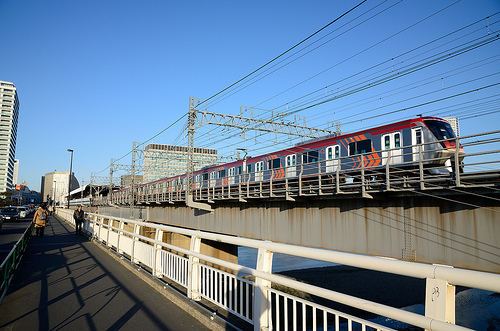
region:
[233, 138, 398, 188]
red and white train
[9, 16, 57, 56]
white clouds in blue sky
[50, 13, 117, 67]
white clouds in blue sky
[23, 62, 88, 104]
white clouds in blue sky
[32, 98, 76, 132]
white clouds in blue sky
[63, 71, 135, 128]
white clouds in blue sky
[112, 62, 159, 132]
white clouds in blue sky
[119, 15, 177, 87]
white clouds in blue sky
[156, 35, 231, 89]
white clouds in blue sky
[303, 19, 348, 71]
white clouds in blue sky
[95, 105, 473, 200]
red and grey train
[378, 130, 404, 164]
pair of white doors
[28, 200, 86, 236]
people walking on the sidewalk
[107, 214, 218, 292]
white guard rail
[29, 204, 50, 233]
person in a brown jacket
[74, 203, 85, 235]
person wearing black clothing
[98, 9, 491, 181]
numerous lines over the train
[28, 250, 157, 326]
shadow cast by the guard rail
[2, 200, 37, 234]
line of cars on the road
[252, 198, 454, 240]
lines of rust on the bridge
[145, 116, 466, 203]
a passenger train on the tracks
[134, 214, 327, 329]
white metal railing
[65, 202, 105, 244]
a man walking along a sidewalk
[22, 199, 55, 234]
a woman in a brown coat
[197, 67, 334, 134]
wires over a passenger train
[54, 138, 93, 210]
a street lamp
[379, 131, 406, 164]
doors to a passenger train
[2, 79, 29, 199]
a tall building in the background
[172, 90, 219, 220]
steel rails that hold electric wires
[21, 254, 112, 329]
a portion of a sidewalk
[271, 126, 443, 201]
red and white train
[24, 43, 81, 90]
white clouds in blue sky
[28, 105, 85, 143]
white clouds in blue sky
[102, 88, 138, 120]
white clouds in blue sky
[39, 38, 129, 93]
white clouds in blue sky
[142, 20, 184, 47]
white clouds in blue sky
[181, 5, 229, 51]
white clouds in blue sky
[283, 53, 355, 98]
white clouds in blue sky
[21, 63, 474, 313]
a scene of the city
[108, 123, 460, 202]
a passenger train for pedestrains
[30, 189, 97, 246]
two people on the bridge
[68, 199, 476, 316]
a bridge for the passenger train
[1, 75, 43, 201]
structures in the background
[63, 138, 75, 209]
a light pole in the area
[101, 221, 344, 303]
a white rail on the bridge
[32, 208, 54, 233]
this person has on a gray backpack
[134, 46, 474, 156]
electric wiring for the passenger car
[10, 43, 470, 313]
a sunny day over the city